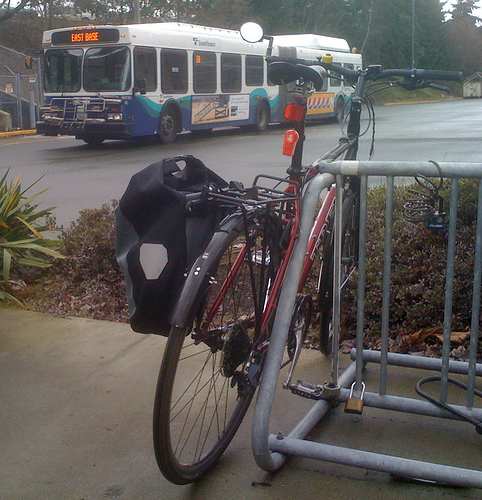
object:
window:
[193, 50, 215, 93]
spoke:
[175, 339, 239, 362]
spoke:
[168, 359, 222, 412]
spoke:
[222, 250, 241, 331]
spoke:
[177, 367, 227, 459]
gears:
[217, 323, 250, 375]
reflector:
[283, 104, 302, 120]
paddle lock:
[348, 377, 365, 402]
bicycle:
[151, 22, 464, 486]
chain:
[221, 308, 311, 400]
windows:
[193, 47, 221, 95]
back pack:
[113, 153, 229, 338]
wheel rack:
[211, 166, 298, 336]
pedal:
[289, 380, 322, 403]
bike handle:
[261, 59, 469, 91]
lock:
[345, 379, 366, 414]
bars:
[250, 158, 479, 487]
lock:
[424, 195, 445, 231]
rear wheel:
[152, 197, 289, 484]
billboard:
[189, 93, 249, 125]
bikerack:
[43, 90, 113, 128]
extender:
[266, 40, 305, 121]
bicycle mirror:
[237, 18, 263, 45]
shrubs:
[54, 195, 122, 285]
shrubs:
[365, 177, 479, 335]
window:
[80, 41, 132, 93]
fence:
[1, 70, 40, 131]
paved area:
[27, 146, 134, 174]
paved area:
[205, 134, 273, 160]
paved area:
[390, 107, 471, 148]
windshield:
[43, 48, 81, 95]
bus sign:
[69, 31, 98, 42]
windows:
[132, 43, 160, 94]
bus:
[32, 21, 365, 144]